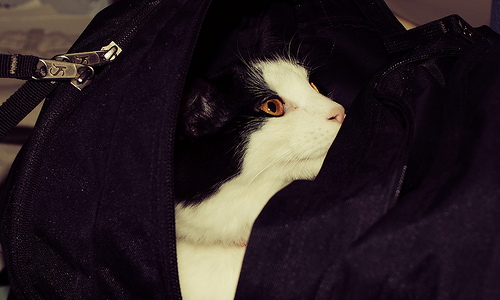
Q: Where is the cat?
A: In a bag.